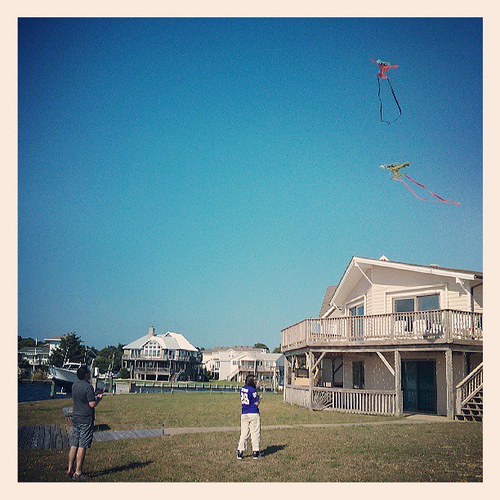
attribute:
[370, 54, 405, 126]
kite — Red 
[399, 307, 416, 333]
chair — white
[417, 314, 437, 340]
chair — white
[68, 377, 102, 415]
shirt — grey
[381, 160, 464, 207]
kite — sky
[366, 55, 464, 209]
kites — colorful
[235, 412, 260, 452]
pants — tan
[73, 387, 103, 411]
shirt — grey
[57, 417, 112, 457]
shorts — grey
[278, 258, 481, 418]
structure — wooden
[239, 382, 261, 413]
blue shirt — blue 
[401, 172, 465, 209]
string — purple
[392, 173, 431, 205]
string — purple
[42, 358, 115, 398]
boat — black, white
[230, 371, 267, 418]
shirt — blue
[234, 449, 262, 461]
sneakers — blue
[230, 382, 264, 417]
jersey — purple 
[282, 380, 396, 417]
fence — wooden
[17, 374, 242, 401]
body water — small 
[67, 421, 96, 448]
shorts — grey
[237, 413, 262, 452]
pants — brown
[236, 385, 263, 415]
shirt — blue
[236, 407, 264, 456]
pants — white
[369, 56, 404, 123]
kite — sky